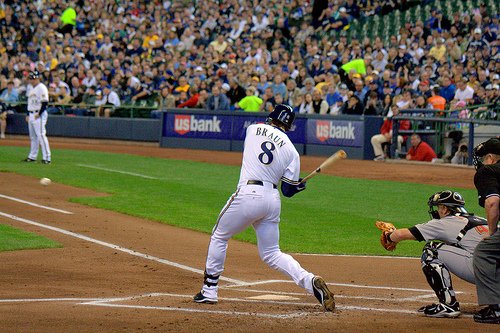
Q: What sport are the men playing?
A: Baseball.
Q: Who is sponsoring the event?
A: US Bank.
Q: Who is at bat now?
A: Braun.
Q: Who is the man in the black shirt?
A: Umpire.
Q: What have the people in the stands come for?
A: To watch the game.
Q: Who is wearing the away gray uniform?
A: Catcher.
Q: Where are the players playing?
A: Baseball stadium.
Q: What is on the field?
A: Grass and dirt.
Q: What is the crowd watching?
A: Baseball game.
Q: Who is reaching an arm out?
A: Catcher.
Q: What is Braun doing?
A: Batting.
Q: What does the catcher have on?
A: Mitt.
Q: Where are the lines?
A: Ground.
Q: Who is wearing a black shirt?
A: Umpire.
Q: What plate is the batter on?
A: Home.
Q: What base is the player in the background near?
A: First.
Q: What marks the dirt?
A: Chalk lines of the baseball diamond.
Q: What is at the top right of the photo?
A: An empty area in the stands.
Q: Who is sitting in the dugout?
A: Coach.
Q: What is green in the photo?
A: Grassy area of the playing field.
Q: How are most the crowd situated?
A: Seated.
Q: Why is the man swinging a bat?
A: To hit ball.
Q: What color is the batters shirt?
A: White.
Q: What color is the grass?
A: Green.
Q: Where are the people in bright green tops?
A: The stands.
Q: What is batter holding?
A: Bat.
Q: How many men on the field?
A: Three.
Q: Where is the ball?
A: In air.